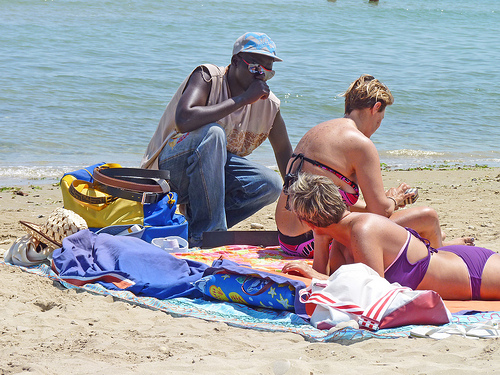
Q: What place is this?
A: It is a beach.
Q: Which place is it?
A: It is a beach.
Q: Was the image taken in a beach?
A: Yes, it was taken in a beach.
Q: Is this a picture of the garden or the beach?
A: It is showing the beach.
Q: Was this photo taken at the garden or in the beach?
A: It was taken at the beach.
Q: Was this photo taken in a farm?
A: No, the picture was taken in a beach.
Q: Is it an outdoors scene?
A: Yes, it is outdoors.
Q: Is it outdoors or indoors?
A: It is outdoors.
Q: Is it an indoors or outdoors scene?
A: It is outdoors.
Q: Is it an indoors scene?
A: No, it is outdoors.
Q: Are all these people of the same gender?
A: No, they are both male and female.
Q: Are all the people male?
A: No, they are both male and female.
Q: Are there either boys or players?
A: No, there are no boys or players.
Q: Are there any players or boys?
A: No, there are no boys or players.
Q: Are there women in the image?
A: Yes, there is a woman.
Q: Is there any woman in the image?
A: Yes, there is a woman.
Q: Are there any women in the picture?
A: Yes, there is a woman.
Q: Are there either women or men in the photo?
A: Yes, there is a woman.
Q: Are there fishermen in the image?
A: No, there are no fishermen.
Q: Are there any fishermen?
A: No, there are no fishermen.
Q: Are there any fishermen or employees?
A: No, there are no fishermen or employees.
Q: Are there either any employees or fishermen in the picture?
A: No, there are no fishermen or employees.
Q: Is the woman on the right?
A: Yes, the woman is on the right of the image.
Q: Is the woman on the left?
A: No, the woman is on the right of the image.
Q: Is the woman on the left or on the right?
A: The woman is on the right of the image.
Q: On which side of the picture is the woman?
A: The woman is on the right of the image.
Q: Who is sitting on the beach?
A: The woman is sitting on the beach.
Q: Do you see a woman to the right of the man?
A: Yes, there is a woman to the right of the man.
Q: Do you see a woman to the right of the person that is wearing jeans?
A: Yes, there is a woman to the right of the man.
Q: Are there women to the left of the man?
A: No, the woman is to the right of the man.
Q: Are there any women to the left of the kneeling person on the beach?
A: No, the woman is to the right of the man.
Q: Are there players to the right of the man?
A: No, there is a woman to the right of the man.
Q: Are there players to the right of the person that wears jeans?
A: No, there is a woman to the right of the man.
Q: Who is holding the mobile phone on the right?
A: The woman is holding the cell phone.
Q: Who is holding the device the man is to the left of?
A: The woman is holding the cell phone.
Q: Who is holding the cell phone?
A: The woman is holding the cell phone.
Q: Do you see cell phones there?
A: Yes, there is a cell phone.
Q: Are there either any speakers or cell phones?
A: Yes, there is a cell phone.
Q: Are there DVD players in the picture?
A: No, there are no DVD players.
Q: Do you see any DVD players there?
A: No, there are no DVD players.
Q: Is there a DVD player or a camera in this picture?
A: No, there are no DVD players or cameras.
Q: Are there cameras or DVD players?
A: No, there are no DVD players or cameras.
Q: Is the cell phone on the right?
A: Yes, the cell phone is on the right of the image.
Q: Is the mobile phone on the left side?
A: No, the mobile phone is on the right of the image.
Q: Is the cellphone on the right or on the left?
A: The cellphone is on the right of the image.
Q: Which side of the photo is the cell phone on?
A: The cell phone is on the right of the image.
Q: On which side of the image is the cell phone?
A: The cell phone is on the right of the image.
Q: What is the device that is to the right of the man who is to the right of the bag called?
A: The device is a cell phone.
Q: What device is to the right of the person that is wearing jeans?
A: The device is a cell phone.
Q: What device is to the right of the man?
A: The device is a cell phone.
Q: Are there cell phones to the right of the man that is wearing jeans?
A: Yes, there is a cell phone to the right of the man.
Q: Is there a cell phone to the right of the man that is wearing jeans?
A: Yes, there is a cell phone to the right of the man.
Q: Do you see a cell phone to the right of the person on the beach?
A: Yes, there is a cell phone to the right of the man.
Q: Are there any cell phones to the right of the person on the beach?
A: Yes, there is a cell phone to the right of the man.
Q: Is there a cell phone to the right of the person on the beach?
A: Yes, there is a cell phone to the right of the man.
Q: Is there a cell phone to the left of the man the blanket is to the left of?
A: No, the cell phone is to the right of the man.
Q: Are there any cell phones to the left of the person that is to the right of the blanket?
A: No, the cell phone is to the right of the man.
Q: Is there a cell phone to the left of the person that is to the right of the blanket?
A: No, the cell phone is to the right of the man.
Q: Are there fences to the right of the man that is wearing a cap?
A: No, there is a cell phone to the right of the man.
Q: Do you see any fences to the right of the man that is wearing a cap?
A: No, there is a cell phone to the right of the man.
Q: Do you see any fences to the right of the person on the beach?
A: No, there is a cell phone to the right of the man.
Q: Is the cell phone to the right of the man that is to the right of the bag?
A: Yes, the cell phone is to the right of the man.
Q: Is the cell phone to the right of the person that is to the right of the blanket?
A: Yes, the cell phone is to the right of the man.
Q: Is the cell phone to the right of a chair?
A: No, the cell phone is to the right of the man.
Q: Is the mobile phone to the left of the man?
A: No, the mobile phone is to the right of the man.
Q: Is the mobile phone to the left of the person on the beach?
A: No, the mobile phone is to the right of the man.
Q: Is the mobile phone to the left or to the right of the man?
A: The mobile phone is to the right of the man.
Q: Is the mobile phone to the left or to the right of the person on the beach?
A: The mobile phone is to the right of the man.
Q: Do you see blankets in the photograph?
A: Yes, there is a blanket.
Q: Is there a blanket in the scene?
A: Yes, there is a blanket.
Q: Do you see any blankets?
A: Yes, there is a blanket.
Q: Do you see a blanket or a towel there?
A: Yes, there is a blanket.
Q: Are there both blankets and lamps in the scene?
A: No, there is a blanket but no lamps.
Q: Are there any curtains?
A: No, there are no curtains.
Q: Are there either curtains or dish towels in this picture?
A: No, there are no curtains or dish towels.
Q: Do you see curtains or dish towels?
A: No, there are no curtains or dish towels.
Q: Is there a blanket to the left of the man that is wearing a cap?
A: Yes, there is a blanket to the left of the man.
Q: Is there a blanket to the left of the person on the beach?
A: Yes, there is a blanket to the left of the man.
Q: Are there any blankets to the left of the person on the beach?
A: Yes, there is a blanket to the left of the man.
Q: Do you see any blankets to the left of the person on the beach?
A: Yes, there is a blanket to the left of the man.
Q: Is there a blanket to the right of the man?
A: No, the blanket is to the left of the man.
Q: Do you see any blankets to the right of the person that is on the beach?
A: No, the blanket is to the left of the man.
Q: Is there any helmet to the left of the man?
A: No, there is a blanket to the left of the man.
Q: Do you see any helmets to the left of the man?
A: No, there is a blanket to the left of the man.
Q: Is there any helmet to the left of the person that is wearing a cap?
A: No, there is a blanket to the left of the man.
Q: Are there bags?
A: Yes, there is a bag.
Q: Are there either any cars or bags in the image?
A: Yes, there is a bag.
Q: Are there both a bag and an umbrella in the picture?
A: No, there is a bag but no umbrellas.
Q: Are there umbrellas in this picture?
A: No, there are no umbrellas.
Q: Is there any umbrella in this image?
A: No, there are no umbrellas.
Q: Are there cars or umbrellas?
A: No, there are no umbrellas or cars.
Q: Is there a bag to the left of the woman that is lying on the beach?
A: Yes, there is a bag to the left of the woman.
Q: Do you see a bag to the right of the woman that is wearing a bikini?
A: No, the bag is to the left of the woman.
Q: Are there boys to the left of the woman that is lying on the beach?
A: No, there is a bag to the left of the woman.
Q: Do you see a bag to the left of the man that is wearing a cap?
A: Yes, there is a bag to the left of the man.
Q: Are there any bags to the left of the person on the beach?
A: Yes, there is a bag to the left of the man.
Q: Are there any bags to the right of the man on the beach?
A: No, the bag is to the left of the man.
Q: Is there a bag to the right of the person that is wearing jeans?
A: No, the bag is to the left of the man.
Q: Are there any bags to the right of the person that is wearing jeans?
A: No, the bag is to the left of the man.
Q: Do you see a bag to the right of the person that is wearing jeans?
A: No, the bag is to the left of the man.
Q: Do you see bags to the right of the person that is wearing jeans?
A: No, the bag is to the left of the man.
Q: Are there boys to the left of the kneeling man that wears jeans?
A: No, there is a bag to the left of the man.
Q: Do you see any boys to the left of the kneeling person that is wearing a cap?
A: No, there is a bag to the left of the man.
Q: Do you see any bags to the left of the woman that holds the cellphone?
A: Yes, there is a bag to the left of the woman.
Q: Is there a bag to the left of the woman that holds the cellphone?
A: Yes, there is a bag to the left of the woman.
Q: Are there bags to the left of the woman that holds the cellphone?
A: Yes, there is a bag to the left of the woman.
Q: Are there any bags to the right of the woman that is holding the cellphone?
A: No, the bag is to the left of the woman.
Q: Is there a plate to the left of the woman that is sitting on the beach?
A: No, there is a bag to the left of the woman.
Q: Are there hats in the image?
A: Yes, there is a hat.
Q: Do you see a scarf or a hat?
A: Yes, there is a hat.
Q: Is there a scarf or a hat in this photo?
A: Yes, there is a hat.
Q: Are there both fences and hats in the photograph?
A: No, there is a hat but no fences.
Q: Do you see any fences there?
A: No, there are no fences.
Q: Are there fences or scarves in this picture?
A: No, there are no fences or scarves.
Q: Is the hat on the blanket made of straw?
A: Yes, the hat is made of straw.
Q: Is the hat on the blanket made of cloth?
A: No, the hat is made of straw.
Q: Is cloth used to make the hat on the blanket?
A: No, the hat is made of straw.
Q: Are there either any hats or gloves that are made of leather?
A: No, there is a hat but it is made of straw.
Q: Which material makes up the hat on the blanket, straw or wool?
A: The hat is made of straw.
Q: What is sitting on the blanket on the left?
A: The hat is sitting on the blanket.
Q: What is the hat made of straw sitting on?
A: The hat is sitting on the blanket.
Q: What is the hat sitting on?
A: The hat is sitting on the blanket.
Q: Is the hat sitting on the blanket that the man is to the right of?
A: Yes, the hat is sitting on the blanket.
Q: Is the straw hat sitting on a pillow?
A: No, the hat is sitting on the blanket.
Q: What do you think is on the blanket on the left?
A: The hat is on the blanket.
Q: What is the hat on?
A: The hat is on the blanket.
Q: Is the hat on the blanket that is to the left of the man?
A: Yes, the hat is on the blanket.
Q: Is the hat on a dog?
A: No, the hat is on the blanket.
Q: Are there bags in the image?
A: Yes, there is a bag.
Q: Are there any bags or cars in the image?
A: Yes, there is a bag.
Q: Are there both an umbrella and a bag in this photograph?
A: No, there is a bag but no umbrellas.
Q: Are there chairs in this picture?
A: No, there are no chairs.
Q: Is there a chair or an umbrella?
A: No, there are no chairs or umbrellas.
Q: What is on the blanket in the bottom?
A: The bag is on the blanket.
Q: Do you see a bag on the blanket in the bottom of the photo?
A: Yes, there is a bag on the blanket.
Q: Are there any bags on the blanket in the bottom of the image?
A: Yes, there is a bag on the blanket.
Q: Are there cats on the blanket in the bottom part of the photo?
A: No, there is a bag on the blanket.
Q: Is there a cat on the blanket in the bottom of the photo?
A: No, there is a bag on the blanket.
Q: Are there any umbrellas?
A: No, there are no umbrellas.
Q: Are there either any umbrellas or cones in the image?
A: No, there are no umbrellas or cones.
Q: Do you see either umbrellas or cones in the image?
A: No, there are no umbrellas or cones.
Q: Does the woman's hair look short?
A: Yes, the hair is short.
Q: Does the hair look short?
A: Yes, the hair is short.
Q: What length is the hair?
A: The hair is short.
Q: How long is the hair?
A: The hair is short.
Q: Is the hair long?
A: No, the hair is short.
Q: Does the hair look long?
A: No, the hair is short.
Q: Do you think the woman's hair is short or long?
A: The hair is short.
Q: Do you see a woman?
A: Yes, there is a woman.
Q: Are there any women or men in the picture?
A: Yes, there is a woman.